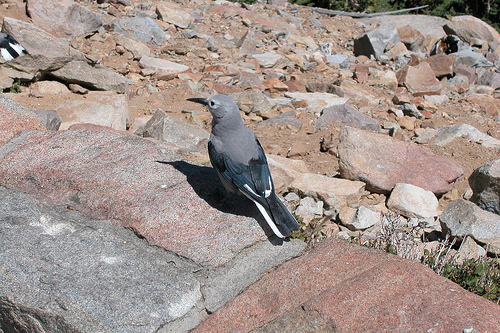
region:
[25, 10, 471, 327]
a bird on the ground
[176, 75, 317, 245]
this bird is gray and black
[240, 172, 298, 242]
the bird's feathers have a white stripe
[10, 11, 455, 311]
colorful rocks on the ground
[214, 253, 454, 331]
a red brick in the shot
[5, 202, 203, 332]
a gray brick in the scene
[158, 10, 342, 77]
brown rocks on the ground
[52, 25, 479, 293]
rugged terrain beneath the bird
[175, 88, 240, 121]
the bird has a black beak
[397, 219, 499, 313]
a patch of green grass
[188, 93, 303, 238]
bird standing on the rock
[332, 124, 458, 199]
large rock on ground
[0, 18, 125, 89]
large rock on ground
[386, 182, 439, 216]
large rock on ground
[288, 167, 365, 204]
large rock on ground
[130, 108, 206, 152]
large rock on ground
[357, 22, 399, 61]
large rock on ground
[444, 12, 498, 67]
large rock on ground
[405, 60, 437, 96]
large rock on ground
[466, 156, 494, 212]
large rock on ground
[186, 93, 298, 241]
the bird is standing on the brick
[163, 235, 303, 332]
grout in the brick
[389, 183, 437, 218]
a white rock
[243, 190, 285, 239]
a white tail feather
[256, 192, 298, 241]
black tail feathers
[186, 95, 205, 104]
the bird beak is black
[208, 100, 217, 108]
a black eye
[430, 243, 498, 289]
a small green bush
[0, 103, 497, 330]
a small brick wall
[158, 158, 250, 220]
the bird's shadow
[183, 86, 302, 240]
A gray bird standing on the rocks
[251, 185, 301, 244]
Tail feathers on a gray bird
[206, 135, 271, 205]
Wing of a gray bird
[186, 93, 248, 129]
The head of a small gray bird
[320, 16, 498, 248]
Rocks down a hill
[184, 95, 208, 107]
A black beak of a bird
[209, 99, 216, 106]
A black eye of a bird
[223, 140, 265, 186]
Feathers on a gray bird's back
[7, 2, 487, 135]
Jagged rocks on a hill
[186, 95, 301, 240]
A small bird on the rocks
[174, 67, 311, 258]
this is a bird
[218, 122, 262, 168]
grey feathers on bird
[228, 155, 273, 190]
dark blue feathers on bird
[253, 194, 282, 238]
white feathers on bird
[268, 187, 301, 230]
black feathers on bird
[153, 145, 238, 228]
a shadow of bird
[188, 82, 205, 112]
beak of a bird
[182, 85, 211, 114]
the birds beak is black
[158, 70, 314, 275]
bird sitting on a rock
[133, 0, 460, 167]
multiple rocks in background